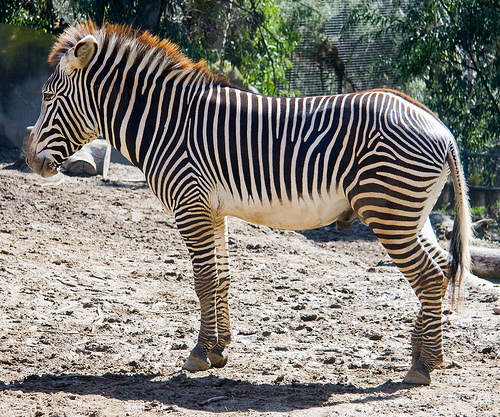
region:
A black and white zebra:
[35, 19, 427, 406]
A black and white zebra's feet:
[375, 216, 462, 393]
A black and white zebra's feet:
[174, 214, 240, 364]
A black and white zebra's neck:
[90, 46, 163, 178]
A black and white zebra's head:
[32, 69, 96, 166]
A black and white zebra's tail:
[451, 151, 486, 274]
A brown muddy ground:
[27, 239, 134, 387]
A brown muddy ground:
[255, 271, 370, 374]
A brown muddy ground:
[456, 321, 491, 410]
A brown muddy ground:
[18, 195, 153, 267]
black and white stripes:
[232, 112, 314, 169]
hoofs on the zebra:
[164, 348, 241, 379]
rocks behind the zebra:
[69, 149, 117, 181]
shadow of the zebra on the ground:
[0, 373, 400, 415]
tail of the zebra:
[443, 147, 477, 310]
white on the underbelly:
[230, 207, 348, 229]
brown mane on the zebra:
[130, 40, 207, 62]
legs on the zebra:
[375, 221, 456, 402]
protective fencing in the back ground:
[291, 42, 408, 93]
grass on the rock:
[4, 28, 35, 78]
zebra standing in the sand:
[20, 13, 487, 394]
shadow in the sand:
[8, 359, 409, 411]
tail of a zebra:
[445, 131, 488, 335]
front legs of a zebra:
[159, 210, 256, 386]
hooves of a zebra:
[174, 347, 236, 371]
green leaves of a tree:
[238, 2, 299, 94]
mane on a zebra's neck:
[75, 16, 209, 87]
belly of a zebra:
[210, 193, 355, 237]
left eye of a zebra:
[37, 83, 61, 106]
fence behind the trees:
[328, 2, 401, 92]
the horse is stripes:
[26, 40, 458, 410]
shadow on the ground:
[41, 360, 266, 413]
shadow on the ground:
[22, 324, 332, 407]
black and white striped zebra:
[23, 13, 473, 390]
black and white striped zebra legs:
[150, 197, 240, 374]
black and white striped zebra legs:
[337, 186, 459, 393]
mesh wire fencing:
[242, 5, 432, 96]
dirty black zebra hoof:
[173, 349, 226, 371]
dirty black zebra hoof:
[201, 344, 231, 369]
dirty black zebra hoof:
[402, 360, 431, 395]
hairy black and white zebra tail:
[438, 137, 473, 314]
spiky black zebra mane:
[35, 9, 234, 85]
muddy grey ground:
[2, 154, 499, 413]